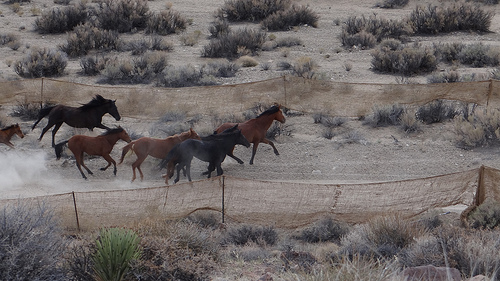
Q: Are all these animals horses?
A: Yes, all the animals are horses.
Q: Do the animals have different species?
A: No, all the animals are horses.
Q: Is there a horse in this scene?
A: Yes, there is a horse.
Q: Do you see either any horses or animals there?
A: Yes, there is a horse.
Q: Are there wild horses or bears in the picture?
A: Yes, there is a wild horse.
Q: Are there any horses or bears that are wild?
A: Yes, the horse is wild.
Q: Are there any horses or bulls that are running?
A: Yes, the horse is running.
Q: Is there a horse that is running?
A: Yes, there is a horse that is running.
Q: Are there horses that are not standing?
A: Yes, there is a horse that is running.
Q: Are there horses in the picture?
A: Yes, there is a horse.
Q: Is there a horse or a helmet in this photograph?
A: Yes, there is a horse.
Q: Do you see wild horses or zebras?
A: Yes, there is a wild horse.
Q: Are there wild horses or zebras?
A: Yes, there is a wild horse.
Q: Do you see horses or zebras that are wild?
A: Yes, the horse is wild.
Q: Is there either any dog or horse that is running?
A: Yes, the horse is running.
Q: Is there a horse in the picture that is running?
A: Yes, there is a horse that is running.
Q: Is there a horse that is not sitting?
A: Yes, there is a horse that is running.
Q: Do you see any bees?
A: No, there are no bees.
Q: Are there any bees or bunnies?
A: No, there are no bees or bunnies.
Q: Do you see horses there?
A: Yes, there is a horse.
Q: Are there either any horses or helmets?
A: Yes, there is a horse.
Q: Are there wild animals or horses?
A: Yes, there is a wild horse.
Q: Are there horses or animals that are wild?
A: Yes, the horse is wild.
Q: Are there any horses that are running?
A: Yes, there is a horse that is running.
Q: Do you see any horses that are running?
A: Yes, there is a horse that is running.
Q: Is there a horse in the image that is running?
A: Yes, there is a horse that is running.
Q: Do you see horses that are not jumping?
A: Yes, there is a horse that is running .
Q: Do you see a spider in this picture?
A: No, there are no spiders.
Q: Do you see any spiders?
A: No, there are no spiders.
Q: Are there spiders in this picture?
A: No, there are no spiders.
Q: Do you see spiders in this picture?
A: No, there are no spiders.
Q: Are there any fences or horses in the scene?
A: Yes, there is a horse.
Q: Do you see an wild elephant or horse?
A: Yes, there is a wild horse.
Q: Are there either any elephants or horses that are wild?
A: Yes, the horse is wild.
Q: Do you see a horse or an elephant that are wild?
A: Yes, the horse is wild.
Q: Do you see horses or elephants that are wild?
A: Yes, the horse is wild.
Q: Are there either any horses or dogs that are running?
A: Yes, the horse is running.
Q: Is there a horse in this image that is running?
A: Yes, there is a horse that is running.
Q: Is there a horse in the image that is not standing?
A: Yes, there is a horse that is running.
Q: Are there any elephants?
A: No, there are no elephants.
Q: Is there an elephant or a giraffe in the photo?
A: No, there are no elephants or giraffes.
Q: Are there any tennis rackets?
A: No, there are no tennis rackets.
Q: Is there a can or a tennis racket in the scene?
A: No, there are no rackets or cans.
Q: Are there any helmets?
A: No, there are no helmets.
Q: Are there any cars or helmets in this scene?
A: No, there are no helmets or cars.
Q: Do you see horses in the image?
A: Yes, there is a horse.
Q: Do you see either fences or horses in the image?
A: Yes, there is a horse.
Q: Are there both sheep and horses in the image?
A: No, there is a horse but no sheep.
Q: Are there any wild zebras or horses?
A: Yes, there is a wild horse.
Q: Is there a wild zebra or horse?
A: Yes, there is a wild horse.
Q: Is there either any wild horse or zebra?
A: Yes, there is a wild horse.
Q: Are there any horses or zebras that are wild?
A: Yes, the horse is wild.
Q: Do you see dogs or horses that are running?
A: Yes, the horse is running.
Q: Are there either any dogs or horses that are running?
A: Yes, the horse is running.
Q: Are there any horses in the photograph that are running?
A: Yes, there is a horse that is running.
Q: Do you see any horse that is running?
A: Yes, there is a horse that is running.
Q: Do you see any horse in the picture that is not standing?
A: Yes, there is a horse that is running .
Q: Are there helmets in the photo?
A: No, there are no helmets.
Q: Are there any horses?
A: Yes, there is a horse.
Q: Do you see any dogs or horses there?
A: Yes, there is a horse.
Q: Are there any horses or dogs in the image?
A: Yes, there is a horse.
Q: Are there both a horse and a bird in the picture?
A: No, there is a horse but no birds.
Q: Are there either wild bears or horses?
A: Yes, there is a wild horse.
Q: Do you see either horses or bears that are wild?
A: Yes, the horse is wild.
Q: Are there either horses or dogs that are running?
A: Yes, the horse is running.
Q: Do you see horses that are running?
A: Yes, there is a horse that is running.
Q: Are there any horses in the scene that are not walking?
A: Yes, there is a horse that is running.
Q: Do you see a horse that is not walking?
A: Yes, there is a horse that is running .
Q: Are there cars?
A: No, there are no cars.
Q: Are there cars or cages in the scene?
A: No, there are no cars or cages.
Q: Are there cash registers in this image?
A: No, there are no cash registers.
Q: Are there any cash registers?
A: No, there are no cash registers.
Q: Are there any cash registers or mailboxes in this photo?
A: No, there are no cash registers or mailboxes.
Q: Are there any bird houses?
A: No, there are no bird houses.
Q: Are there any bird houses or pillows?
A: No, there are no bird houses or pillows.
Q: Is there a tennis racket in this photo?
A: No, there are no rackets.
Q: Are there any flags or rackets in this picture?
A: No, there are no rackets or flags.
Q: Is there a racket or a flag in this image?
A: No, there are no rackets or flags.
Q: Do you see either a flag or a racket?
A: No, there are no rackets or flags.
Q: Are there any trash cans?
A: No, there are no trash cans.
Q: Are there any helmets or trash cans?
A: No, there are no trash cans or helmets.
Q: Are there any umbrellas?
A: No, there are no umbrellas.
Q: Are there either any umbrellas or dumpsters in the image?
A: No, there are no umbrellas or dumpsters.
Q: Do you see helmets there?
A: No, there are no helmets.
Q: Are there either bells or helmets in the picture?
A: No, there are no helmets or bells.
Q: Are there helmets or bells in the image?
A: No, there are no helmets or bells.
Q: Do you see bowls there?
A: No, there are no bowls.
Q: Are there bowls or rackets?
A: No, there are no bowls or rackets.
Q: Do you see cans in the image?
A: No, there are no cans.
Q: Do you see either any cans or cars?
A: No, there are no cans or cars.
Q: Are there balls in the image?
A: No, there are no balls.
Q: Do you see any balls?
A: No, there are no balls.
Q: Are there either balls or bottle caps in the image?
A: No, there are no balls or bottle caps.